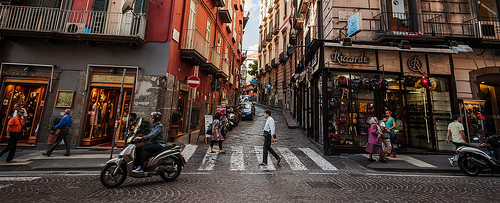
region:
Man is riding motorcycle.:
[95, 105, 186, 195]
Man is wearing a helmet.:
[145, 98, 168, 134]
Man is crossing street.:
[252, 100, 283, 175]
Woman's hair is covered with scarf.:
[362, 107, 381, 131]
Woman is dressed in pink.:
[362, 122, 384, 158]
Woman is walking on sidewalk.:
[359, 112, 388, 172]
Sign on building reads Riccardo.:
[322, 46, 379, 73]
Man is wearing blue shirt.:
[39, 105, 79, 134]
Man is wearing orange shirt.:
[6, 114, 28, 138]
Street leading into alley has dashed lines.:
[162, 130, 359, 185]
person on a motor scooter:
[95, 107, 192, 184]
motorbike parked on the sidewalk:
[446, 135, 498, 172]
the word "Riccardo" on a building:
[330, 47, 376, 67]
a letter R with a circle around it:
[404, 53, 426, 73]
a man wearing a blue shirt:
[41, 104, 77, 160]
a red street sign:
[185, 71, 204, 92]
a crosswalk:
[166, 137, 336, 176]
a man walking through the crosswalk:
[260, 109, 282, 168]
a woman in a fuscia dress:
[366, 113, 383, 160]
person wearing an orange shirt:
[6, 106, 26, 161]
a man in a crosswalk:
[257, 104, 280, 169]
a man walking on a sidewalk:
[40, 106, 75, 163]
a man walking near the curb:
[0, 102, 25, 167]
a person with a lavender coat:
[364, 111, 391, 166]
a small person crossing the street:
[204, 108, 225, 161]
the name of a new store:
[319, 45, 377, 70]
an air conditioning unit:
[471, 20, 497, 40]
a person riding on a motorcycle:
[97, 108, 185, 189]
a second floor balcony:
[0, 0, 147, 45]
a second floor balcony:
[373, 0, 498, 45]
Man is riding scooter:
[101, 109, 193, 184]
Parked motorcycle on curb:
[448, 142, 499, 174]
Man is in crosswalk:
[241, 104, 292, 173]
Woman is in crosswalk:
[201, 106, 233, 158]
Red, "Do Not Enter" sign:
[185, 71, 203, 146]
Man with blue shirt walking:
[43, 102, 79, 161]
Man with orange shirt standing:
[2, 105, 27, 162]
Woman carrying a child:
[379, 109, 396, 133]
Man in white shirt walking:
[443, 112, 466, 156]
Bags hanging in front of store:
[323, 43, 455, 105]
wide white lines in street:
[210, 149, 342, 176]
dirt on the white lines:
[227, 154, 244, 179]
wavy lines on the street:
[275, 178, 401, 199]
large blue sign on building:
[343, 10, 372, 47]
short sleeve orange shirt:
[2, 116, 35, 133]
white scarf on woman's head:
[355, 109, 381, 127]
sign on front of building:
[321, 43, 389, 70]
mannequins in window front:
[77, 70, 122, 133]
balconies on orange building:
[213, 16, 259, 81]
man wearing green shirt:
[375, 112, 409, 135]